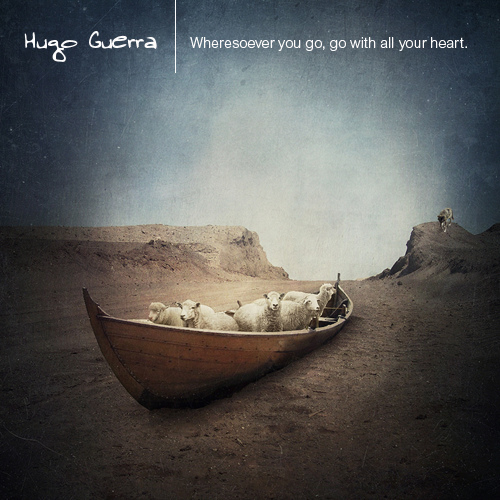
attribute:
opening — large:
[249, 224, 414, 280]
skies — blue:
[262, 150, 433, 212]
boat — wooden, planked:
[15, 251, 403, 413]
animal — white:
[233, 289, 284, 337]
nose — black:
[272, 303, 279, 308]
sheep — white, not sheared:
[145, 281, 340, 334]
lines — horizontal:
[106, 331, 286, 356]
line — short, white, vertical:
[174, 0, 176, 75]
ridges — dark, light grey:
[2, 216, 499, 280]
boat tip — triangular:
[48, 267, 138, 381]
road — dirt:
[158, 247, 340, 281]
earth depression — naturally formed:
[153, 161, 493, 341]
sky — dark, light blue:
[39, 44, 480, 251]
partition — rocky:
[4, 227, 498, 495]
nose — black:
[181, 312, 188, 322]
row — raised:
[70, 237, 219, 285]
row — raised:
[125, 218, 257, 246]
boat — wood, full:
[79, 272, 359, 413]